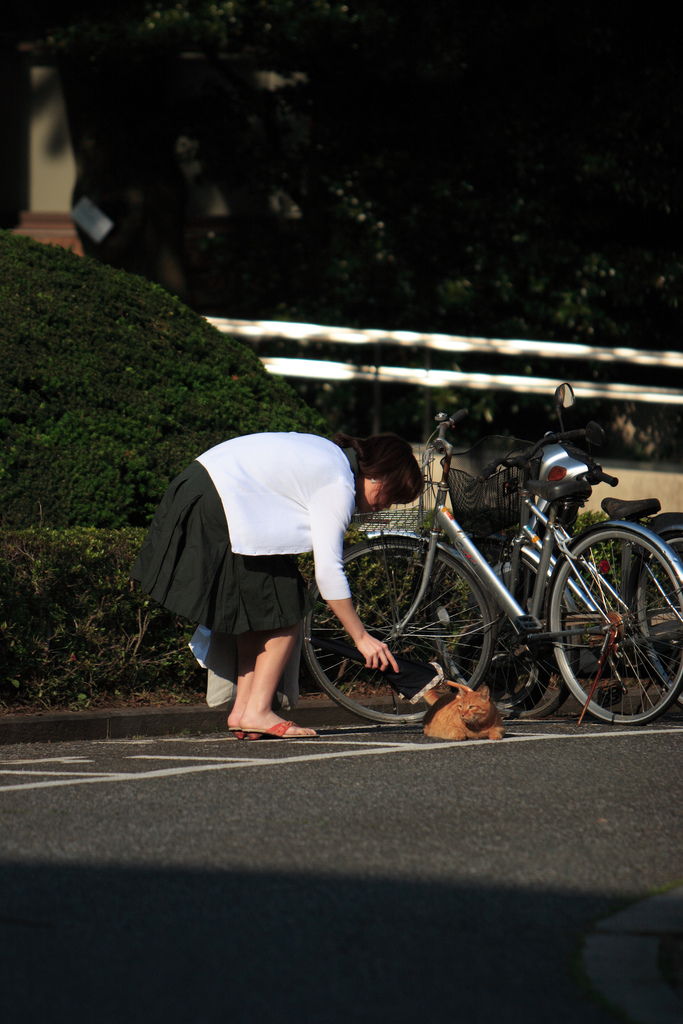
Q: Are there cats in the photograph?
A: Yes, there is a cat.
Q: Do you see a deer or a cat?
A: Yes, there is a cat.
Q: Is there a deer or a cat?
A: Yes, there is a cat.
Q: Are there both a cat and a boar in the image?
A: No, there is a cat but no boars.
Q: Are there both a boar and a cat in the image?
A: No, there is a cat but no boars.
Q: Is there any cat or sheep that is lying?
A: Yes, the cat is lying.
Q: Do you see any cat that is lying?
A: Yes, there is a cat that is lying.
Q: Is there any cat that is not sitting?
A: Yes, there is a cat that is lying.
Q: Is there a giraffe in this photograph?
A: No, there are no giraffes.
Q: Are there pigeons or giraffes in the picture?
A: No, there are no giraffes or pigeons.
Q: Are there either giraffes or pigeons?
A: No, there are no giraffes or pigeons.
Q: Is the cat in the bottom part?
A: Yes, the cat is in the bottom of the image.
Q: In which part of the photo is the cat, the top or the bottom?
A: The cat is in the bottom of the image.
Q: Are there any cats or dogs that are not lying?
A: No, there is a cat but it is lying.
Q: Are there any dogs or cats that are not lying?
A: No, there is a cat but it is lying.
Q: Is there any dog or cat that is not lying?
A: No, there is a cat but it is lying.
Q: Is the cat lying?
A: Yes, the cat is lying.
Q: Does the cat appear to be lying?
A: Yes, the cat is lying.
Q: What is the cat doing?
A: The cat is lying.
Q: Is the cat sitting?
A: No, the cat is lying.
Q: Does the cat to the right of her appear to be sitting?
A: No, the cat is lying.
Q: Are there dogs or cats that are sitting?
A: No, there is a cat but it is lying.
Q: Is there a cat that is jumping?
A: No, there is a cat but it is lying.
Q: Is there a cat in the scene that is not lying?
A: No, there is a cat but it is lying.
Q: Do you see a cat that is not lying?
A: No, there is a cat but it is lying.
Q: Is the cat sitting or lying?
A: The cat is lying.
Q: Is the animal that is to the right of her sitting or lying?
A: The cat is lying.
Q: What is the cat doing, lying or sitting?
A: The cat is lying.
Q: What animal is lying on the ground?
A: The animal is a cat.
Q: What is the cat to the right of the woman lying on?
A: The cat is lying on the ground.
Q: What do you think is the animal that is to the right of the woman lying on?
A: The cat is lying on the ground.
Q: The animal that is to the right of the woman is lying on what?
A: The cat is lying on the ground.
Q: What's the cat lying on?
A: The cat is lying on the ground.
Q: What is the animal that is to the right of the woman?
A: The animal is a cat.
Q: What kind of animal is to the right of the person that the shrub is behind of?
A: The animal is a cat.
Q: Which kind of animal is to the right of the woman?
A: The animal is a cat.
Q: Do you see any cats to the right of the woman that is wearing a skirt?
A: Yes, there is a cat to the right of the woman.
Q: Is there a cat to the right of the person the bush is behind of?
A: Yes, there is a cat to the right of the woman.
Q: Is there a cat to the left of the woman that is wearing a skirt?
A: No, the cat is to the right of the woman.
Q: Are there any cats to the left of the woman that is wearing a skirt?
A: No, the cat is to the right of the woman.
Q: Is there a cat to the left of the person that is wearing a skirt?
A: No, the cat is to the right of the woman.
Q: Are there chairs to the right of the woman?
A: No, there is a cat to the right of the woman.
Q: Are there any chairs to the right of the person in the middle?
A: No, there is a cat to the right of the woman.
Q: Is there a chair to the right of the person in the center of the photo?
A: No, there is a cat to the right of the woman.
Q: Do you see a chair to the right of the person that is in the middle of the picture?
A: No, there is a cat to the right of the woman.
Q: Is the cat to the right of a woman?
A: Yes, the cat is to the right of a woman.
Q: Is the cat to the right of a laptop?
A: No, the cat is to the right of a woman.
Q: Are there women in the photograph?
A: Yes, there is a woman.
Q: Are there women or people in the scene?
A: Yes, there is a woman.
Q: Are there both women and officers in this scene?
A: No, there is a woman but no officers.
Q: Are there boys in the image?
A: No, there are no boys.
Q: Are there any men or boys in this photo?
A: No, there are no boys or men.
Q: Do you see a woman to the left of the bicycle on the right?
A: Yes, there is a woman to the left of the bicycle.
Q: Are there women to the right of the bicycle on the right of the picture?
A: No, the woman is to the left of the bicycle.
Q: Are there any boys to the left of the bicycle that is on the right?
A: No, there is a woman to the left of the bicycle.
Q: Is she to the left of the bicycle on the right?
A: Yes, the woman is to the left of the bicycle.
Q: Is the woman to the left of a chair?
A: No, the woman is to the left of the bicycle.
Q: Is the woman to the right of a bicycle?
A: No, the woman is to the left of a bicycle.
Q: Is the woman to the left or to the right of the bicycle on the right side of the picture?
A: The woman is to the left of the bicycle.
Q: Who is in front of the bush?
A: The woman is in front of the shrub.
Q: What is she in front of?
A: The woman is in front of the shrub.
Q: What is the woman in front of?
A: The woman is in front of the shrub.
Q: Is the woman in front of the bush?
A: Yes, the woman is in front of the bush.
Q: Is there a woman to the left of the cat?
A: Yes, there is a woman to the left of the cat.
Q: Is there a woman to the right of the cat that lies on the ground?
A: No, the woman is to the left of the cat.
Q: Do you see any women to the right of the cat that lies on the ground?
A: No, the woman is to the left of the cat.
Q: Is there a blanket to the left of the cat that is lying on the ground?
A: No, there is a woman to the left of the cat.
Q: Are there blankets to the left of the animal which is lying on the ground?
A: No, there is a woman to the left of the cat.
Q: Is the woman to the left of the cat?
A: Yes, the woman is to the left of the cat.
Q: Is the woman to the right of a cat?
A: No, the woman is to the left of a cat.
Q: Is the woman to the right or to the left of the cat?
A: The woman is to the left of the cat.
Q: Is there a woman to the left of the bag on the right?
A: Yes, there is a woman to the left of the bag.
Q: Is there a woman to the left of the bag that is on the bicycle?
A: Yes, there is a woman to the left of the bag.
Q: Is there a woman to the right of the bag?
A: No, the woman is to the left of the bag.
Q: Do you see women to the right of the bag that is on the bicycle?
A: No, the woman is to the left of the bag.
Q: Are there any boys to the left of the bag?
A: No, there is a woman to the left of the bag.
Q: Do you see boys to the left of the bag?
A: No, there is a woman to the left of the bag.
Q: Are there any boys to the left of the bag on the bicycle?
A: No, there is a woman to the left of the bag.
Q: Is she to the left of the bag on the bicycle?
A: Yes, the woman is to the left of the bag.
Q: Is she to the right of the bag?
A: No, the woman is to the left of the bag.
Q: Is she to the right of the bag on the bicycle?
A: No, the woman is to the left of the bag.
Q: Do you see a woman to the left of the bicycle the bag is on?
A: Yes, there is a woman to the left of the bicycle.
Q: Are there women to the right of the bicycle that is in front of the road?
A: No, the woman is to the left of the bicycle.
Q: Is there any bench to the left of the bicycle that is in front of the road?
A: No, there is a woman to the left of the bicycle.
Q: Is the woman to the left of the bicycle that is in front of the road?
A: Yes, the woman is to the left of the bicycle.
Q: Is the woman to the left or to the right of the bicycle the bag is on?
A: The woman is to the left of the bicycle.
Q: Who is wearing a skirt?
A: The woman is wearing a skirt.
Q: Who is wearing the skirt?
A: The woman is wearing a skirt.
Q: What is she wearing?
A: The woman is wearing a skirt.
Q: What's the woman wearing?
A: The woman is wearing a skirt.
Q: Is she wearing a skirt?
A: Yes, the woman is wearing a skirt.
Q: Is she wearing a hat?
A: No, the woman is wearing a skirt.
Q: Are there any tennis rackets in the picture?
A: No, there are no tennis rackets.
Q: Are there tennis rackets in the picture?
A: No, there are no tennis rackets.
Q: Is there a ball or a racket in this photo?
A: No, there are no rackets or balls.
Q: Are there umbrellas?
A: Yes, there is an umbrella.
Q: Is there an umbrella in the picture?
A: Yes, there is an umbrella.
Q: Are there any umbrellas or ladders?
A: Yes, there is an umbrella.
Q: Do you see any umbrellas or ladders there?
A: Yes, there is an umbrella.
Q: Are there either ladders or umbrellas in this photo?
A: Yes, there is an umbrella.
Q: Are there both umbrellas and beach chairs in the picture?
A: No, there is an umbrella but no beach chairs.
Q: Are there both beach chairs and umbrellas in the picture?
A: No, there is an umbrella but no beach chairs.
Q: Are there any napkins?
A: No, there are no napkins.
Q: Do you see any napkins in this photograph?
A: No, there are no napkins.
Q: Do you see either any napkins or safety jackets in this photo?
A: No, there are no napkins or safety jackets.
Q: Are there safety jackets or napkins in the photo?
A: No, there are no napkins or safety jackets.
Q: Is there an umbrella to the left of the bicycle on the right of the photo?
A: Yes, there is an umbrella to the left of the bicycle.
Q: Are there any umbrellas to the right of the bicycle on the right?
A: No, the umbrella is to the left of the bicycle.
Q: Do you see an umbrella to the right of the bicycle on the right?
A: No, the umbrella is to the left of the bicycle.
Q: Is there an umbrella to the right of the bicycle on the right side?
A: No, the umbrella is to the left of the bicycle.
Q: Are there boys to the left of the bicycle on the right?
A: No, there is an umbrella to the left of the bicycle.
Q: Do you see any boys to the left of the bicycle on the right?
A: No, there is an umbrella to the left of the bicycle.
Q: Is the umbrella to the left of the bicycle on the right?
A: Yes, the umbrella is to the left of the bicycle.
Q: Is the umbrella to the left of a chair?
A: No, the umbrella is to the left of the bicycle.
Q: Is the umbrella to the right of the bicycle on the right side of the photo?
A: No, the umbrella is to the left of the bicycle.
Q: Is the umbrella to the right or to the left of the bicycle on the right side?
A: The umbrella is to the left of the bicycle.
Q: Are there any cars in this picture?
A: No, there are no cars.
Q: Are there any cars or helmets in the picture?
A: No, there are no cars or helmets.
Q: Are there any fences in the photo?
A: Yes, there is a fence.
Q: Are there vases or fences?
A: Yes, there is a fence.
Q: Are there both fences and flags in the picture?
A: No, there is a fence but no flags.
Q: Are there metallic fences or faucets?
A: Yes, there is a metal fence.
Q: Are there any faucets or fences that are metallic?
A: Yes, the fence is metallic.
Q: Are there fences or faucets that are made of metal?
A: Yes, the fence is made of metal.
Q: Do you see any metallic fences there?
A: Yes, there is a metal fence.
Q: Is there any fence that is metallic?
A: Yes, there is a fence that is metallic.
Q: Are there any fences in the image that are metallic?
A: Yes, there is a fence that is metallic.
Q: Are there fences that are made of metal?
A: Yes, there is a fence that is made of metal.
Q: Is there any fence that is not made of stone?
A: Yes, there is a fence that is made of metal.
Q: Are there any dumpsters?
A: No, there are no dumpsters.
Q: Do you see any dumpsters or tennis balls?
A: No, there are no dumpsters or tennis balls.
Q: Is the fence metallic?
A: Yes, the fence is metallic.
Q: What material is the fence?
A: The fence is made of metal.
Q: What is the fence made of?
A: The fence is made of metal.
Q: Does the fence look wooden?
A: No, the fence is metallic.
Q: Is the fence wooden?
A: No, the fence is metallic.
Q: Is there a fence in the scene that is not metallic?
A: No, there is a fence but it is metallic.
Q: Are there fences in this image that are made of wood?
A: No, there is a fence but it is made of metal.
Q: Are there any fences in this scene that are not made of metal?
A: No, there is a fence but it is made of metal.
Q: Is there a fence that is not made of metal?
A: No, there is a fence but it is made of metal.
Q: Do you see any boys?
A: No, there are no boys.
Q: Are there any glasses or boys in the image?
A: No, there are no boys or glasses.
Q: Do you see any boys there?
A: No, there are no boys.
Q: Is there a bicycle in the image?
A: Yes, there is a bicycle.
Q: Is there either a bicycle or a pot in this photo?
A: Yes, there is a bicycle.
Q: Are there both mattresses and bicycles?
A: No, there is a bicycle but no mattresses.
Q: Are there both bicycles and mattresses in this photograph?
A: No, there is a bicycle but no mattresses.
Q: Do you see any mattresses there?
A: No, there are no mattresses.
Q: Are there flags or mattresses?
A: No, there are no mattresses or flags.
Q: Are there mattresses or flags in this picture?
A: No, there are no mattresses or flags.